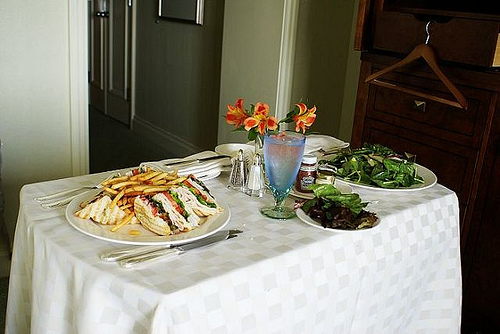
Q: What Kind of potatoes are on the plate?
A: French fries.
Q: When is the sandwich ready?
A: Now.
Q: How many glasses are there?
A: One.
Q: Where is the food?
A: On the table.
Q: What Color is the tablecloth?
A: White.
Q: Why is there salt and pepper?
A: Flavor.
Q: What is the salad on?
A: Plates.